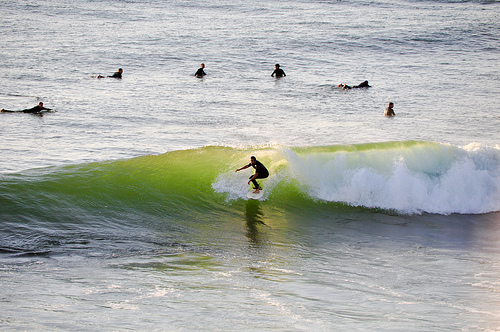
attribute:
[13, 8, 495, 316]
ocean — rippled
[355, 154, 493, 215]
foam — white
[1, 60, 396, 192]
wet suits — black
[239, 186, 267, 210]
surfboard — white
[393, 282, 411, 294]
ocean ripple — rippled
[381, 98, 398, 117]
man — bare chested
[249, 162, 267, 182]
suit — is wet